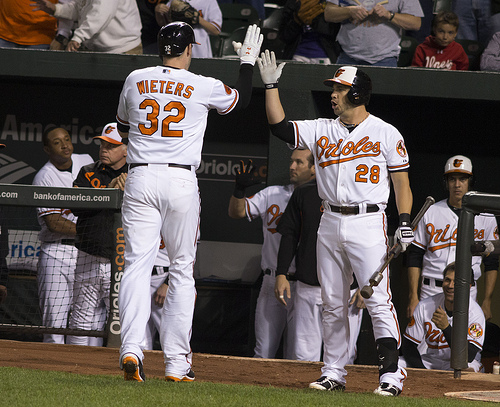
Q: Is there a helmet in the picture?
A: Yes, there is a helmet.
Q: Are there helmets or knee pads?
A: Yes, there is a helmet.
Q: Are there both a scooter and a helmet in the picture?
A: No, there is a helmet but no scooters.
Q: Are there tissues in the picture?
A: No, there are no tissues.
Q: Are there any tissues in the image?
A: No, there are no tissues.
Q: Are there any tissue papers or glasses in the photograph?
A: No, there are no tissue papers or glasses.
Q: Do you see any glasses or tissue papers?
A: No, there are no tissue papers or glasses.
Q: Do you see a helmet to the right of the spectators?
A: Yes, there is a helmet to the right of the spectators.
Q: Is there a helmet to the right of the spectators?
A: Yes, there is a helmet to the right of the spectators.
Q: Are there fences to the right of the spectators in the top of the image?
A: No, there is a helmet to the right of the spectators.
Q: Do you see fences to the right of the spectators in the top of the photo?
A: No, there is a helmet to the right of the spectators.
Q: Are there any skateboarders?
A: No, there are no skateboarders.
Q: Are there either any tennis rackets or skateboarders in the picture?
A: No, there are no skateboarders or tennis rackets.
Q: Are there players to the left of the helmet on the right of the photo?
A: Yes, there is a player to the left of the helmet.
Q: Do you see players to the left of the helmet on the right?
A: Yes, there is a player to the left of the helmet.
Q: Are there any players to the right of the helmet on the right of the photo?
A: No, the player is to the left of the helmet.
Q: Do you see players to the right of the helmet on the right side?
A: No, the player is to the left of the helmet.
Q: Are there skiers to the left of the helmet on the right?
A: No, there is a player to the left of the helmet.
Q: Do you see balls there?
A: No, there are no balls.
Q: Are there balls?
A: No, there are no balls.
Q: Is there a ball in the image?
A: No, there are no balls.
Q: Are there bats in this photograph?
A: Yes, there is a bat.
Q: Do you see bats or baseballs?
A: Yes, there is a bat.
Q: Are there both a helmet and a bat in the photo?
A: Yes, there are both a bat and a helmet.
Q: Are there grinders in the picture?
A: No, there are no grinders.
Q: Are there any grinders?
A: No, there are no grinders.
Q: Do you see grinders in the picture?
A: No, there are no grinders.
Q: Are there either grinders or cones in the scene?
A: No, there are no grinders or cones.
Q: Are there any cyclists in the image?
A: No, there are no cyclists.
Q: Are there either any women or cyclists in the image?
A: No, there are no cyclists or women.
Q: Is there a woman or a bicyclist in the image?
A: No, there are no cyclists or women.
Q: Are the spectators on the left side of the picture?
A: Yes, the spectators are on the left of the image.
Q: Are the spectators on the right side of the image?
A: No, the spectators are on the left of the image.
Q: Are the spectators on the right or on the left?
A: The spectators are on the left of the image.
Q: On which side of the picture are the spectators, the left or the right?
A: The spectators are on the left of the image.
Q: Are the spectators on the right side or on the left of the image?
A: The spectators are on the left of the image.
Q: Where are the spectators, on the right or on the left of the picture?
A: The spectators are on the left of the image.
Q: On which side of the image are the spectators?
A: The spectators are on the left of the image.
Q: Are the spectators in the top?
A: Yes, the spectators are in the top of the image.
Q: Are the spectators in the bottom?
A: No, the spectators are in the top of the image.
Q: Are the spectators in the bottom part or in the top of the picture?
A: The spectators are in the top of the image.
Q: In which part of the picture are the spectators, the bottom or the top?
A: The spectators are in the top of the image.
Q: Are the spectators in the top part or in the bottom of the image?
A: The spectators are in the top of the image.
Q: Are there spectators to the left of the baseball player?
A: Yes, there are spectators to the left of the player.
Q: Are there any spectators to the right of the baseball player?
A: No, the spectators are to the left of the player.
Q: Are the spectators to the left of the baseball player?
A: Yes, the spectators are to the left of the player.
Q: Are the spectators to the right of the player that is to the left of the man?
A: No, the spectators are to the left of the player.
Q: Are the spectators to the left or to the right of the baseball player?
A: The spectators are to the left of the player.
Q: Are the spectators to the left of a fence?
A: No, the spectators are to the left of the helmet.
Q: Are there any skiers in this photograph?
A: No, there are no skiers.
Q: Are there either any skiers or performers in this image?
A: No, there are no skiers or performers.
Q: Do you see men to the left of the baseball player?
A: Yes, there is a man to the left of the player.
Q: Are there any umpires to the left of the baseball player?
A: No, there is a man to the left of the player.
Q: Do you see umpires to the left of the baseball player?
A: No, there is a man to the left of the player.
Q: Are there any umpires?
A: No, there are no umpires.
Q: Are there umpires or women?
A: No, there are no umpires or women.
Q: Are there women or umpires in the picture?
A: No, there are no umpires or women.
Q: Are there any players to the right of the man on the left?
A: Yes, there is a player to the right of the man.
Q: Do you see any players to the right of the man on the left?
A: Yes, there is a player to the right of the man.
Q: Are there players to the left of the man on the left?
A: No, the player is to the right of the man.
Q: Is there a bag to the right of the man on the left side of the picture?
A: No, there is a player to the right of the man.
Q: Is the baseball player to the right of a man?
A: Yes, the player is to the right of a man.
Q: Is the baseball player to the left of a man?
A: No, the player is to the right of a man.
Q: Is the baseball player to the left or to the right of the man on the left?
A: The player is to the right of the man.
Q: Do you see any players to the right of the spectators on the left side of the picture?
A: Yes, there is a player to the right of the spectators.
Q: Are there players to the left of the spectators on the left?
A: No, the player is to the right of the spectators.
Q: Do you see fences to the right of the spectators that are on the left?
A: No, there is a player to the right of the spectators.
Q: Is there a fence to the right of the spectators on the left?
A: No, there is a player to the right of the spectators.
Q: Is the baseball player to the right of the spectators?
A: Yes, the player is to the right of the spectators.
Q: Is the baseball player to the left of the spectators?
A: No, the player is to the right of the spectators.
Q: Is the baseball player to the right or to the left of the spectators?
A: The player is to the right of the spectators.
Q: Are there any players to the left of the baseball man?
A: Yes, there is a player to the left of the man.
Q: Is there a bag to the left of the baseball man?
A: No, there is a player to the left of the man.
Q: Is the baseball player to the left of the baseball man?
A: Yes, the player is to the left of the man.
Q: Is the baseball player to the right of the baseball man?
A: No, the player is to the left of the man.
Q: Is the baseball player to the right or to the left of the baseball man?
A: The player is to the left of the man.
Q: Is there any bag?
A: No, there are no bags.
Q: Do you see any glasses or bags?
A: No, there are no bags or glasses.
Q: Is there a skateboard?
A: No, there are no skateboards.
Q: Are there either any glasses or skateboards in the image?
A: No, there are no skateboards or glasses.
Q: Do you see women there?
A: No, there are no women.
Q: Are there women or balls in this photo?
A: No, there are no women or balls.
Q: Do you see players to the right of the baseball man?
A: Yes, there is a player to the right of the man.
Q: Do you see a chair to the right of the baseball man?
A: No, there is a player to the right of the man.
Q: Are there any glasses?
A: No, there are no glasses.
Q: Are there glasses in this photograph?
A: No, there are no glasses.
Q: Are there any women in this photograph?
A: No, there are no women.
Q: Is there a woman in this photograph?
A: No, there are no women.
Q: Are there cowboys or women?
A: No, there are no women or cowboys.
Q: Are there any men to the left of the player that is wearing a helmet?
A: Yes, there is a man to the left of the player.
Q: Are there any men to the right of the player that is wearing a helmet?
A: No, the man is to the left of the player.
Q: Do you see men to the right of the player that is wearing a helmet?
A: No, the man is to the left of the player.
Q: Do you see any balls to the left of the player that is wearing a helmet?
A: No, there is a man to the left of the player.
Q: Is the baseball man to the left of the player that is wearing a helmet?
A: Yes, the man is to the left of the player.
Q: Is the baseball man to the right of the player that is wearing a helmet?
A: No, the man is to the left of the player.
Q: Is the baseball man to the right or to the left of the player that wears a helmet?
A: The man is to the left of the player.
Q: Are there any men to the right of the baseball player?
A: Yes, there is a man to the right of the player.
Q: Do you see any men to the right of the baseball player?
A: Yes, there is a man to the right of the player.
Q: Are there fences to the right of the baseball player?
A: No, there is a man to the right of the player.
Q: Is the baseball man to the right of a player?
A: Yes, the man is to the right of a player.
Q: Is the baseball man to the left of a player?
A: No, the man is to the right of a player.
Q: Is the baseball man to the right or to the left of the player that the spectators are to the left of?
A: The man is to the right of the player.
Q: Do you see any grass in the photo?
A: Yes, there is grass.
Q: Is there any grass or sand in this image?
A: Yes, there is grass.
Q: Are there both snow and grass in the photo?
A: No, there is grass but no snow.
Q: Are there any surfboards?
A: No, there are no surfboards.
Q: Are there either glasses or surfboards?
A: No, there are no surfboards or glasses.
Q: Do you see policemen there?
A: No, there are no policemen.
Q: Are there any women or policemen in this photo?
A: No, there are no policemen or women.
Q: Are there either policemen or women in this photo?
A: No, there are no policemen or women.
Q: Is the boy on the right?
A: Yes, the boy is on the right of the image.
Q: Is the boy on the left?
A: No, the boy is on the right of the image.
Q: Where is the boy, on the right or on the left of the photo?
A: The boy is on the right of the image.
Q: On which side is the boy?
A: The boy is on the right of the image.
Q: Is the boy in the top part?
A: Yes, the boy is in the top of the image.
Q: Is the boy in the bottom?
A: No, the boy is in the top of the image.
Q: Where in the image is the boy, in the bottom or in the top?
A: The boy is in the top of the image.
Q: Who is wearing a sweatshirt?
A: The boy is wearing a sweatshirt.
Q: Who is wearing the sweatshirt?
A: The boy is wearing a sweatshirt.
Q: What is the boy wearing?
A: The boy is wearing a sweatshirt.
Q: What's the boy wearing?
A: The boy is wearing a sweatshirt.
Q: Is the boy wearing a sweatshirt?
A: Yes, the boy is wearing a sweatshirt.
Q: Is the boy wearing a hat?
A: No, the boy is wearing a sweatshirt.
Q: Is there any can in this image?
A: No, there are no cans.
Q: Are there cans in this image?
A: No, there are no cans.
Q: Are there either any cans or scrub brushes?
A: No, there are no cans or scrub brushes.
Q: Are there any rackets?
A: No, there are no rackets.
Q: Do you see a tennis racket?
A: No, there are no rackets.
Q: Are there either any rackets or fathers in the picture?
A: No, there are no rackets or fathers.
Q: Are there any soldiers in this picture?
A: No, there are no soldiers.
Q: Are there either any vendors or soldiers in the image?
A: No, there are no soldiers or vendors.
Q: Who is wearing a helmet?
A: The player is wearing a helmet.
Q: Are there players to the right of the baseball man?
A: Yes, there is a player to the right of the man.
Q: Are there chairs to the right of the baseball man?
A: No, there is a player to the right of the man.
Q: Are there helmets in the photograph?
A: Yes, there is a helmet.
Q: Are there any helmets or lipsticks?
A: Yes, there is a helmet.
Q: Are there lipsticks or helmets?
A: Yes, there is a helmet.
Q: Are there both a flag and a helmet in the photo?
A: No, there is a helmet but no flags.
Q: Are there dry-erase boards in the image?
A: No, there are no dry-erase boards.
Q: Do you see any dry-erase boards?
A: No, there are no dry-erase boards.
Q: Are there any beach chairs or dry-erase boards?
A: No, there are no dry-erase boards or beach chairs.